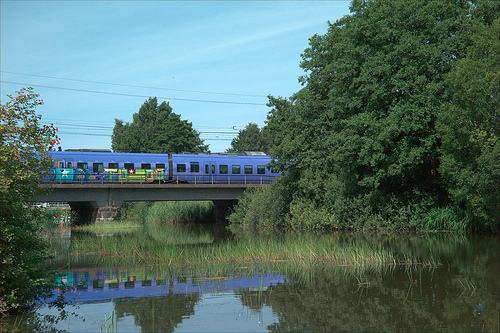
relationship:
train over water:
[9, 148, 296, 188] [12, 221, 484, 327]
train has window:
[9, 148, 296, 188] [191, 161, 200, 175]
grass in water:
[117, 235, 438, 273] [12, 221, 484, 327]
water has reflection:
[12, 221, 484, 327] [28, 255, 295, 303]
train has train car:
[9, 148, 296, 188] [172, 151, 299, 182]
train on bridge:
[9, 148, 296, 188] [7, 181, 274, 222]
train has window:
[9, 148, 296, 188] [94, 161, 105, 175]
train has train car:
[9, 148, 296, 188] [31, 150, 170, 184]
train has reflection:
[9, 148, 296, 188] [28, 255, 295, 303]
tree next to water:
[266, 0, 482, 245] [12, 221, 484, 327]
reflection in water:
[28, 255, 295, 303] [12, 221, 484, 327]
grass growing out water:
[117, 235, 438, 273] [12, 221, 484, 327]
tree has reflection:
[266, 0, 482, 245] [251, 232, 497, 330]